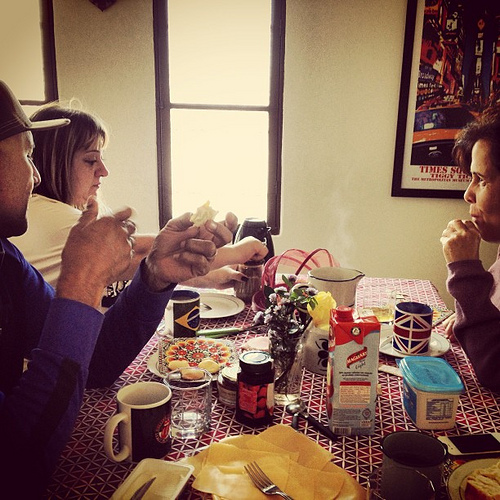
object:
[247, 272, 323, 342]
flowers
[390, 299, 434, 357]
mug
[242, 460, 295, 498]
fork table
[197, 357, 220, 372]
cookies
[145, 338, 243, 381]
plate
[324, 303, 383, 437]
carton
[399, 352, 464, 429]
carton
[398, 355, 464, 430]
butter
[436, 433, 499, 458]
cell phone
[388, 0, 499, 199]
picture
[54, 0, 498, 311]
wall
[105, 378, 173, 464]
mug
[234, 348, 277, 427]
jelly jar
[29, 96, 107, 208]
brown hair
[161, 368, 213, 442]
glass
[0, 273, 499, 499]
table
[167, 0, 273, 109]
window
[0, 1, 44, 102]
window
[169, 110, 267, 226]
window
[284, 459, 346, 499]
napkin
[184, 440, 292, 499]
napkin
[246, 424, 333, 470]
napkin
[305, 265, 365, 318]
pitcher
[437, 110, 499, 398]
person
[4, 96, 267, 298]
person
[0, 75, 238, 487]
person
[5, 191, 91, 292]
shirt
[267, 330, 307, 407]
vase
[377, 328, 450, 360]
plate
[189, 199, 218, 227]
bread